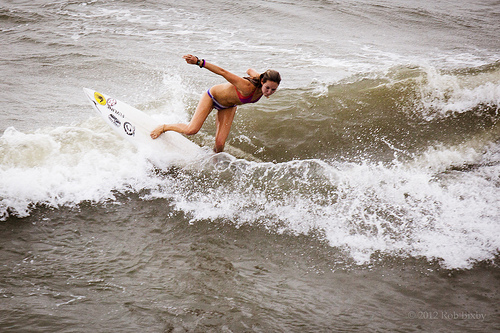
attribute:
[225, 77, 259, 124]
bikini top — red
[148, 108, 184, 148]
foot — bare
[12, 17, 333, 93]
ocean — calm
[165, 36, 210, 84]
bands — colorful